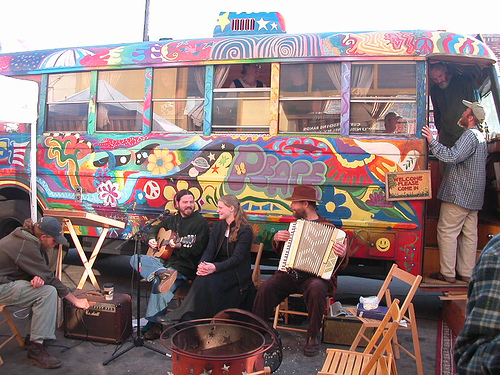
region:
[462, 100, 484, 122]
The man is wearing a cap.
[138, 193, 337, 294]
People sitting by the bus.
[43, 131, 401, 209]
The bus is a gypsy bus.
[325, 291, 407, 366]
The woden chair is empty.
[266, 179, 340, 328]
The man is playing an instrument.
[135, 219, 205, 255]
The man is playing a guitar.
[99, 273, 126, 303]
Coffee cup on the amplifier.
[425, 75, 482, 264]
Two men standing on the bus.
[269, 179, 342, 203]
A man wearing a brown hat.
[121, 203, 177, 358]
A microphone in front of the man.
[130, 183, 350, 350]
the musicians by the bus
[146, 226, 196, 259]
the guitar in the mans hands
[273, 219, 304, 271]
the keys on the accordion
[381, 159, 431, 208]
the welcome sign on the bus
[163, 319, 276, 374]
the fire pit by the chair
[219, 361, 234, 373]
the hole shaped like a star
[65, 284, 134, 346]
the amplifier on the ground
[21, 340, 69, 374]
the brown boot on the foot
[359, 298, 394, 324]
the blue book on the chair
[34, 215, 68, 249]
the grey hat on the persons head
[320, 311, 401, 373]
a small wooden folding chair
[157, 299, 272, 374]
a small red fire pit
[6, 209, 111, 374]
a man that is fiddling with an amp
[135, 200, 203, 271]
a man playing an accustic guitar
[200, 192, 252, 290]
a young blonde woman smiling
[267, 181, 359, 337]
a man in a top hat playing an accordion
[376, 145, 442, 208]
a sign welcoming people to come in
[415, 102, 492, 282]
a man that is walking into a bus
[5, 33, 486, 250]
a large and colorful hippy bus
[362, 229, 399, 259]
a sticker that has a smiley face on it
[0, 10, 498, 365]
people near a large former school bus painted with bright designs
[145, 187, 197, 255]
man playing a guitar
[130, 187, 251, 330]
man looking at woman seated beside him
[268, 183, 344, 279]
man playing an accordion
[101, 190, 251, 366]
microphone on stand in front of man and woman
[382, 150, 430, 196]
sign hung on bus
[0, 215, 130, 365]
man reaching down towards a speaker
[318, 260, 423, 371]
two wooden folding chairs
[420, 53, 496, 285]
man standing in entrance of bus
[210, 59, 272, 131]
woman standing in bus seen through open window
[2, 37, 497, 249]
this is a bus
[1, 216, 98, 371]
this is a person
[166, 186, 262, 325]
this is a person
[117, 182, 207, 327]
this is a person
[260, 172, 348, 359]
this is a person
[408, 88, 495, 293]
this is a person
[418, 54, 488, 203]
this is a person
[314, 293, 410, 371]
this is a chair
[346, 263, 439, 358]
this is a chair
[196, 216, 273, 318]
this is a chair